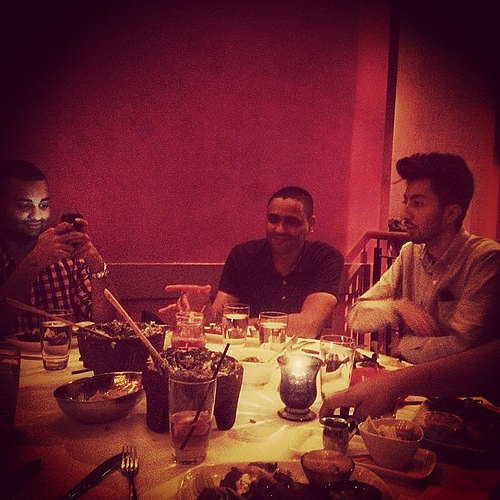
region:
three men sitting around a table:
[2, 147, 498, 369]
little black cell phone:
[56, 210, 89, 255]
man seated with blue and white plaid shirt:
[0, 160, 105, 335]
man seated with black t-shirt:
[160, 181, 345, 336]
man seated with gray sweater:
[346, 147, 497, 379]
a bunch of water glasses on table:
[38, 302, 363, 454]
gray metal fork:
[118, 442, 144, 498]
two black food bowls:
[78, 315, 245, 429]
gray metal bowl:
[53, 367, 150, 421]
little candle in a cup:
[276, 352, 323, 422]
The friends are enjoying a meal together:
[10, 110, 490, 487]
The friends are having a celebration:
[6, 127, 488, 463]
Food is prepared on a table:
[5, 148, 496, 470]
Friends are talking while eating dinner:
[17, 127, 487, 483]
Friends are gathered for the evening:
[11, 110, 487, 485]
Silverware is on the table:
[25, 132, 475, 492]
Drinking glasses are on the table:
[25, 127, 485, 497]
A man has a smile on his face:
[261, 185, 309, 251]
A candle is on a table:
[267, 346, 323, 419]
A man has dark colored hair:
[395, 150, 477, 245]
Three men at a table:
[6, 135, 498, 495]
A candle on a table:
[273, 350, 320, 427]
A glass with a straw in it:
[165, 339, 232, 456]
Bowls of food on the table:
[61, 296, 243, 408]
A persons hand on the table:
[311, 325, 498, 446]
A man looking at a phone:
[4, 150, 116, 323]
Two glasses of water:
[224, 293, 294, 349]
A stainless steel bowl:
[59, 367, 142, 424]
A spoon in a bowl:
[97, 283, 192, 382]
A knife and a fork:
[62, 441, 162, 498]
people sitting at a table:
[16, 127, 491, 443]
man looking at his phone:
[2, 156, 116, 283]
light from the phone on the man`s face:
[8, 178, 65, 231]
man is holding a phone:
[44, 204, 92, 257]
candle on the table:
[257, 325, 319, 410]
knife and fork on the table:
[60, 432, 152, 490]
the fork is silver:
[100, 437, 148, 488]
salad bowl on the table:
[111, 327, 251, 419]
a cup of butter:
[350, 404, 426, 471]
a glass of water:
[16, 295, 86, 366]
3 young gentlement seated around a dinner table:
[3, 106, 494, 496]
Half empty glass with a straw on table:
[163, 340, 233, 462]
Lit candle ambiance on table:
[272, 350, 322, 420]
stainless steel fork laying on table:
[115, 440, 140, 495]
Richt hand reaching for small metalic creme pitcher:
[315, 380, 385, 450]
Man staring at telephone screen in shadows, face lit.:
[0, 160, 115, 335]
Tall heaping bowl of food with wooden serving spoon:
[102, 284, 247, 432]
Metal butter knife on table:
[51, 447, 133, 499]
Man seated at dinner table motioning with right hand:
[156, 182, 344, 342]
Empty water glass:
[316, 330, 358, 400]